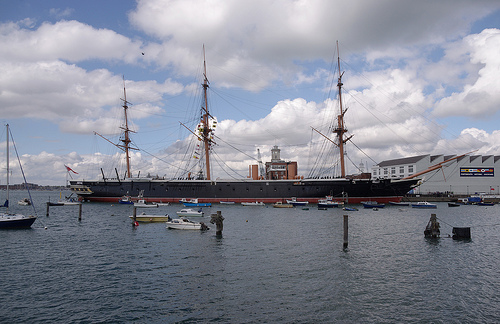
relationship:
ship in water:
[54, 45, 482, 212] [6, 185, 499, 314]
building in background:
[375, 152, 500, 196] [1, 0, 500, 204]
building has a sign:
[375, 152, 500, 196] [460, 168, 495, 175]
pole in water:
[344, 216, 351, 251] [6, 185, 499, 314]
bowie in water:
[135, 222, 141, 229] [6, 185, 499, 314]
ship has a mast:
[54, 45, 482, 212] [334, 39, 351, 178]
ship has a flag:
[54, 45, 482, 212] [194, 107, 204, 162]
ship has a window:
[54, 45, 482, 212] [218, 186, 222, 190]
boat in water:
[166, 217, 202, 229] [6, 185, 499, 314]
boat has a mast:
[166, 217, 202, 229] [334, 39, 351, 178]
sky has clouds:
[0, 0, 499, 188] [132, 3, 497, 67]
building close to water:
[375, 152, 500, 196] [6, 185, 499, 314]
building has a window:
[375, 152, 500, 196] [408, 164, 413, 176]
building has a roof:
[375, 152, 500, 196] [379, 154, 431, 166]